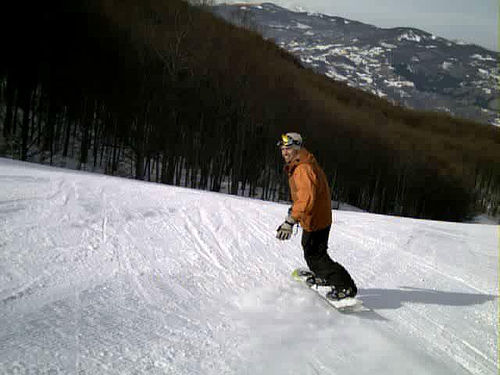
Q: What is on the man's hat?
A: Goggles.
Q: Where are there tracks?
A: In the snow.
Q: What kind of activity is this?
A: Snowboarding.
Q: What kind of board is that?
A: A snowboard.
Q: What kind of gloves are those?
A: Grey gloves.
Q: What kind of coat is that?
A: An orange coat.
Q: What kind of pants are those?
A: Black pants.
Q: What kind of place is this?
A: A snowy field surrounded by trees.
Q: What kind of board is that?
A: A white snowboard.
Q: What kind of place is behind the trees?
A: A mountain.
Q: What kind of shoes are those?
A: Black shoes.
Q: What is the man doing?
A: Riding a snowboard while smiling.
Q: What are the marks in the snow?
A: Tracks.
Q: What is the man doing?
A: Snowboarding.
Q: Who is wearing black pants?
A: The man.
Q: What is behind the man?
A: Trees.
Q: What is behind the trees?
A: A Mountain.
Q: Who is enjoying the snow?
A: The man.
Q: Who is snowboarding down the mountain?
A: The man.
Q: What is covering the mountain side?
A: Trees.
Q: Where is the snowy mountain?
A: Behind the trees.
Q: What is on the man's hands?
A: Gloves.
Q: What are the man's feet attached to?
A: Snowboard.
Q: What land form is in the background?
A: Mountian.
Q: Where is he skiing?
A: On the slope.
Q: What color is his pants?
A: Black.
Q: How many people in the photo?
A: One.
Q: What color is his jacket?
A: Orange.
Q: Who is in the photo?
A: Man.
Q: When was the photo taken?
A: Winter.